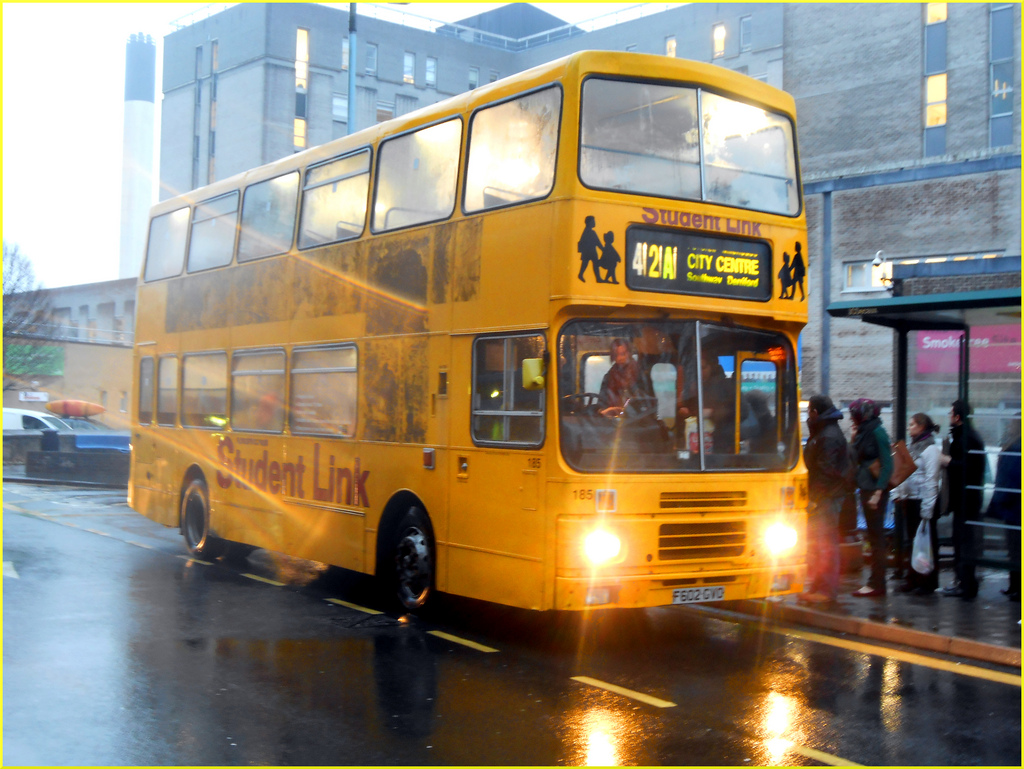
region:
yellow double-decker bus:
[119, 45, 821, 638]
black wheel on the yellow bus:
[362, 494, 443, 621]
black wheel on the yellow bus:
[176, 462, 215, 555]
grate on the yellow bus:
[659, 484, 757, 580]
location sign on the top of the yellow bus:
[621, 226, 774, 303]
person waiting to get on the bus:
[807, 396, 859, 573]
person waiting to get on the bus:
[849, 390, 904, 606]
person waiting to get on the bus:
[899, 406, 947, 606]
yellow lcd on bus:
[631, 235, 777, 290]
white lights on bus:
[570, 508, 859, 627]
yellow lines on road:
[509, 648, 745, 750]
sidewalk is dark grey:
[810, 566, 1017, 656]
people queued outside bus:
[792, 402, 1008, 627]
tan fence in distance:
[5, 279, 133, 398]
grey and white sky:
[32, 16, 108, 235]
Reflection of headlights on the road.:
[544, 680, 742, 764]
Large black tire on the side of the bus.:
[386, 481, 456, 595]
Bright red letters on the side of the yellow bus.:
[187, 411, 409, 525]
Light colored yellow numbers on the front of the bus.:
[629, 221, 772, 305]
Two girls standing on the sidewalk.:
[877, 373, 1002, 627]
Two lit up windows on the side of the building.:
[915, 0, 961, 140]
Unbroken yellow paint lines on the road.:
[550, 657, 699, 747]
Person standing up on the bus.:
[585, 303, 661, 434]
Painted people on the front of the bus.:
[573, 215, 628, 293]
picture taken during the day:
[13, 9, 1022, 649]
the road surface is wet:
[59, 556, 238, 692]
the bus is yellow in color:
[128, 101, 799, 621]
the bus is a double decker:
[132, 141, 816, 613]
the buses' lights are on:
[577, 490, 808, 583]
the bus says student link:
[199, 438, 395, 518]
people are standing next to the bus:
[818, 378, 993, 581]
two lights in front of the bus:
[585, 498, 804, 572]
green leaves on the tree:
[39, 293, 46, 345]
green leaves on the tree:
[15, 331, 74, 388]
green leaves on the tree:
[24, 287, 75, 387]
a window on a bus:
[470, 325, 543, 462]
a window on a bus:
[286, 338, 369, 443]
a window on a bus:
[181, 349, 226, 423]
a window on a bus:
[135, 354, 167, 432]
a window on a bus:
[151, 200, 187, 270]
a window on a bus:
[191, 190, 237, 273]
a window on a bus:
[241, 175, 306, 255]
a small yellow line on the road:
[555, 650, 692, 730]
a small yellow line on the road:
[755, 720, 877, 766]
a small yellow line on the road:
[410, 622, 516, 667]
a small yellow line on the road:
[315, 579, 391, 622]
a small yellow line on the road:
[234, 554, 296, 597]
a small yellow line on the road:
[166, 537, 221, 575]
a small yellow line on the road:
[116, 525, 164, 557]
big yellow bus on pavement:
[149, 209, 764, 584]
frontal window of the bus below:
[558, 319, 790, 474]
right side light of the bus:
[578, 518, 630, 572]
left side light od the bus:
[758, 514, 801, 566]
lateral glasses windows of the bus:
[141, 356, 363, 434]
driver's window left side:
[467, 332, 550, 457]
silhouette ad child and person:
[574, 205, 619, 297]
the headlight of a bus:
[577, 518, 620, 570]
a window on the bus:
[471, 338, 548, 421]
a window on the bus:
[234, 326, 276, 403]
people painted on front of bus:
[563, 187, 646, 309]